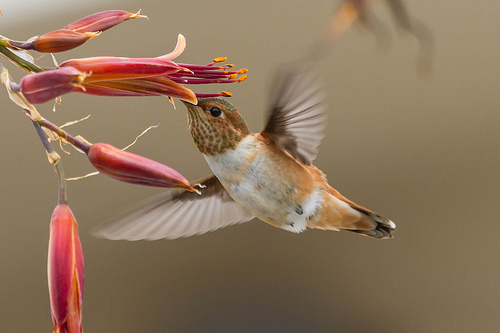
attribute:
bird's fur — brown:
[222, 128, 314, 214]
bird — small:
[82, 33, 405, 240]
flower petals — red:
[21, 60, 93, 102]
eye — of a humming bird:
[210, 102, 222, 118]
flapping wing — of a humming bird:
[265, 51, 333, 167]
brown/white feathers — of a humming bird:
[229, 156, 319, 216]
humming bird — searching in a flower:
[88, 63, 397, 250]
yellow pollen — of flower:
[214, 55, 248, 102]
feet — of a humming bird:
[289, 200, 304, 230]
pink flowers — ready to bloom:
[13, 4, 148, 51]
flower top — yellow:
[203, 51, 252, 102]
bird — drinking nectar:
[83, 55, 400, 242]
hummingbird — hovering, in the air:
[120, 64, 419, 262]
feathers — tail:
[338, 187, 398, 244]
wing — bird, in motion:
[261, 64, 337, 163]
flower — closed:
[47, 203, 87, 331]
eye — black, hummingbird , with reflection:
[210, 100, 223, 119]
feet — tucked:
[273, 201, 305, 231]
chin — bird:
[199, 119, 230, 149]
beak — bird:
[183, 95, 203, 113]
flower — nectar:
[62, 50, 252, 100]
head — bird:
[180, 83, 260, 160]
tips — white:
[88, 217, 233, 241]